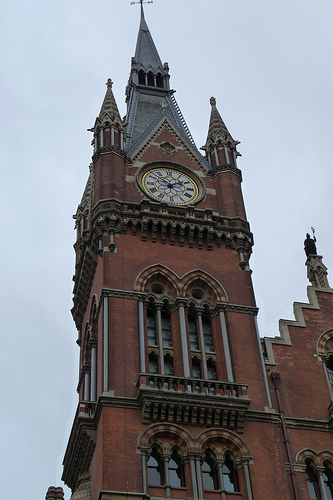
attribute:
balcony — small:
[130, 369, 259, 437]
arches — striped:
[129, 261, 272, 300]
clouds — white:
[16, 60, 67, 123]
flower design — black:
[155, 175, 184, 197]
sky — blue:
[10, 17, 100, 79]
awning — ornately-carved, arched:
[135, 421, 253, 460]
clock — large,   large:
[133, 160, 206, 207]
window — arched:
[135, 416, 204, 498]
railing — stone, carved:
[126, 368, 258, 436]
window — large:
[143, 305, 160, 348]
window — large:
[161, 305, 175, 348]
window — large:
[145, 348, 160, 384]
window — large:
[159, 349, 177, 379]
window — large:
[186, 351, 206, 380]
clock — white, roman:
[139, 164, 199, 207]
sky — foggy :
[4, 225, 59, 412]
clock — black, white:
[136, 155, 205, 206]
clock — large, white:
[141, 167, 199, 205]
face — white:
[160, 169, 218, 206]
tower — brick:
[43, 0, 328, 499]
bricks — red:
[254, 425, 280, 495]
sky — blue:
[2, 1, 327, 307]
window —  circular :
[144, 276, 177, 298]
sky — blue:
[1, 1, 332, 499]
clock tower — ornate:
[62, 2, 290, 498]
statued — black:
[301, 224, 317, 253]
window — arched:
[130, 280, 265, 391]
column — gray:
[102, 297, 108, 392]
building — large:
[27, 17, 300, 497]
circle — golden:
[154, 174, 188, 197]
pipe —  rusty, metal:
[268, 369, 297, 499]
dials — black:
[159, 175, 182, 188]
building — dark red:
[43, 1, 332, 498]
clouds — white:
[204, 11, 282, 67]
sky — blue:
[0, 0, 331, 178]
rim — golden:
[130, 158, 209, 206]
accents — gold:
[144, 165, 199, 203]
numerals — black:
[153, 165, 191, 189]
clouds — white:
[2, 302, 64, 386]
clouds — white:
[195, 30, 307, 91]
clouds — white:
[251, 68, 328, 178]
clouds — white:
[7, 27, 99, 123]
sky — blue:
[0, 1, 330, 348]